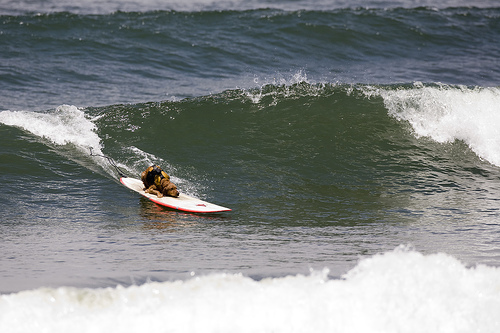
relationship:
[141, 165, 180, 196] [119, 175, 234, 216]
dog riding surfboard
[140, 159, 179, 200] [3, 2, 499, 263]
dog in water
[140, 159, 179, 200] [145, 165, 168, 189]
dog wearing life jacket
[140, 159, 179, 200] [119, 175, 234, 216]
dog on top of surfboard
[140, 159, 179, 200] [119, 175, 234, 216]
dog laying on surfboard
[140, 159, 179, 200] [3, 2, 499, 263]
dog on water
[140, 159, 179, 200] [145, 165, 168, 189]
dog wearing a life jacket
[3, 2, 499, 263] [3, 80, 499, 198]
water with wave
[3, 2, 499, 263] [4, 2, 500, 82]
water with wave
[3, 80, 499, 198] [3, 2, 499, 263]
wave in water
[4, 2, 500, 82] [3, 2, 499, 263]
wave in water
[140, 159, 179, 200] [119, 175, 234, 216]
dog on a surfboard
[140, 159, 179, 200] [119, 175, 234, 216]
dog riding a surfboard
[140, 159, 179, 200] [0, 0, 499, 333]
dog surfing in water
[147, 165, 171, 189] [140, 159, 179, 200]
life jacket on dog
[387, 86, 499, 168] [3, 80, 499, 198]
seafoam on wave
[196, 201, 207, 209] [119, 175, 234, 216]
logo on surfboard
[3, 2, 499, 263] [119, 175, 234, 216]
water by surfboard